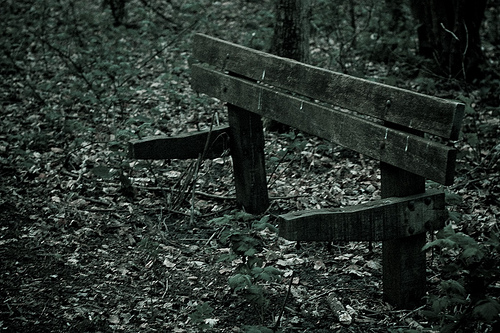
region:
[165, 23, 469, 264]
bench without seat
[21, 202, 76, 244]
green and brown leaves on ground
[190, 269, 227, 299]
green and brown leaves on ground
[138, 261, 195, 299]
green and brown leaves on ground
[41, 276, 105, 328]
green and brown leaves on ground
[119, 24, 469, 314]
Wooden bench with no seat.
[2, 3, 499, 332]
Wooded area with leaves littering the ground.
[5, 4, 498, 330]
A broken bench sitting on ground covered with leaves.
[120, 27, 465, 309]
Bench with only wooden slats on the back.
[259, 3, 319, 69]
The base of a tree.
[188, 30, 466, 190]
Two wooden slats.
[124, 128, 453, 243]
Arms to hold the seat of a bench, which is missing.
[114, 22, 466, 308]
Broken bench in wooded area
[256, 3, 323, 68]
tree behind broken bench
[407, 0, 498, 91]
tree behind broken bench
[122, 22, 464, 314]
broken bench surrounded by dead leaves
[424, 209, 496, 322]
small plants growing by broken bench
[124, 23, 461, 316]
wooden bench missing seat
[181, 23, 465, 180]
back of broken wooden bench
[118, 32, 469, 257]
Park bench in the woods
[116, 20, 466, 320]
Park bench in the woods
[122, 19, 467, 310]
Park bench in the woods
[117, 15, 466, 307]
Wooden bench in the middle of the woods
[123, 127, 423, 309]
Wooden bench has no seat on it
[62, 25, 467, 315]
Bench is made of wood, bolts and nuts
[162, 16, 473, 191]
Seat back on bench is comprised of 2 wooden slats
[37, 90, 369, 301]
Tree branches have been scattered on the ground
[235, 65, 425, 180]
Remnants of bird wait are on the bench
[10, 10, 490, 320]
Picture taken on a cloudy and gloomy day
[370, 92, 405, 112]
Metal lag bot on the seat backing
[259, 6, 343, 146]
Tree trunk behind the wooden bench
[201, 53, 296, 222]
4 by 4 piece of wood used for the legs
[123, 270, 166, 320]
leaves on the ground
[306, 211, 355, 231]
wood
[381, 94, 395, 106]
bolts in the wood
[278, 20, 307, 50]
bark on the tree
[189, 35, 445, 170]
wooden trellis bench on the ground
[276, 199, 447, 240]
wooden bench in front of the pole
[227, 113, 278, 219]
wooden pole above ground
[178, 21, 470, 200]
wooden slats on back of bench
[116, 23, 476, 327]
wooden bench missing the seat portion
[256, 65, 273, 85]
white mark on wooden slats of bench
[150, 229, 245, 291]
leaves on ground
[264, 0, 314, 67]
thin tree trunk behind bench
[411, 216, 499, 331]
small green plant next to bench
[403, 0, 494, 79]
thick brown tree trunk behind bench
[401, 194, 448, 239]
large white splotch on side of bench slat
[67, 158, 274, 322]
Leaves are on the ground